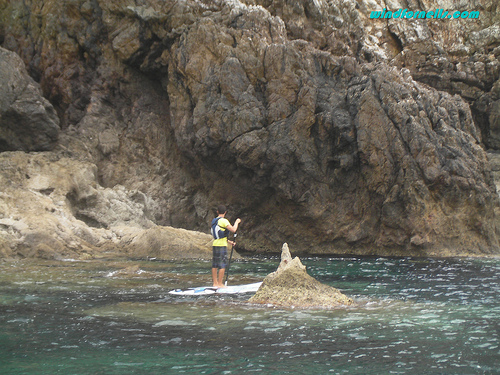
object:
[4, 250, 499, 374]
river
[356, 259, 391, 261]
wave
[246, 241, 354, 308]
rock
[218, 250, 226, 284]
leg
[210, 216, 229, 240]
life vest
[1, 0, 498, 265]
formation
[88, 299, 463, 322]
sand bar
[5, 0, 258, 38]
cliff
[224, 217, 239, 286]
oar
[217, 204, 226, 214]
hair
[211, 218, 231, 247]
shirt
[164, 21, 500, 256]
hill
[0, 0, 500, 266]
landscape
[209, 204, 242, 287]
boy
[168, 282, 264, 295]
paddle board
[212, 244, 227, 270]
shorts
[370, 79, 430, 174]
indentation